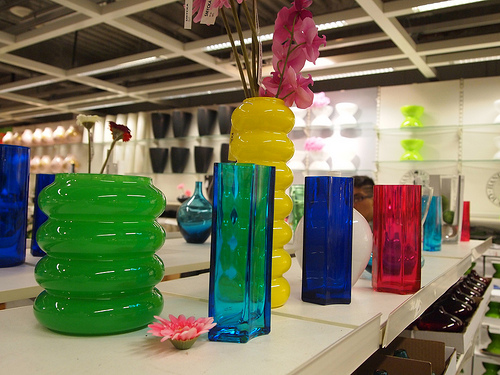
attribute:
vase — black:
[150, 113, 170, 140]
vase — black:
[166, 111, 189, 141]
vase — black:
[194, 109, 215, 136]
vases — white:
[301, 100, 373, 178]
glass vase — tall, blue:
[210, 164, 270, 340]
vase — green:
[40, 154, 158, 330]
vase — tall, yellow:
[224, 105, 294, 309]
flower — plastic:
[152, 294, 207, 343]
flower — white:
[79, 110, 97, 191]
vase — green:
[64, 179, 156, 310]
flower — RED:
[101, 116, 133, 174]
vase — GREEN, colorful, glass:
[34, 167, 171, 330]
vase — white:
[292, 203, 381, 291]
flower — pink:
[252, 7, 333, 111]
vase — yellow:
[226, 87, 303, 315]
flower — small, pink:
[143, 308, 225, 352]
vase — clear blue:
[215, 163, 275, 341]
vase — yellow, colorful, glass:
[218, 93, 306, 312]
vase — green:
[44, 170, 168, 340]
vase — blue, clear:
[207, 158, 273, 348]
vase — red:
[370, 173, 424, 306]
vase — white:
[291, 188, 378, 293]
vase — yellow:
[232, 93, 302, 323]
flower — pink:
[243, 3, 339, 110]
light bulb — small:
[429, 312, 469, 338]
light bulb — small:
[443, 293, 473, 316]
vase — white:
[291, 177, 385, 305]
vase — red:
[371, 177, 425, 290]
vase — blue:
[305, 173, 357, 307]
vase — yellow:
[222, 93, 305, 325]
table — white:
[28, 207, 437, 368]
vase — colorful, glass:
[203, 158, 288, 345]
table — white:
[62, 178, 465, 370]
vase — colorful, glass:
[298, 170, 364, 316]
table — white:
[102, 227, 482, 365]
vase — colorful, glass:
[366, 176, 433, 301]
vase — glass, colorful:
[412, 184, 453, 261]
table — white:
[127, 221, 483, 361]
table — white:
[108, 239, 483, 372]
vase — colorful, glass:
[450, 194, 482, 254]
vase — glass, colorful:
[171, 176, 222, 249]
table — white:
[1, 223, 477, 373]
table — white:
[94, 282, 476, 373]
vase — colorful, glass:
[25, 155, 65, 254]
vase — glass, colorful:
[1, 143, 31, 275]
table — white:
[32, 213, 481, 373]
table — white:
[110, 167, 480, 358]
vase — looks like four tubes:
[26, 163, 170, 336]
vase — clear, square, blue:
[204, 144, 281, 347]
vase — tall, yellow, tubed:
[228, 95, 293, 309]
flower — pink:
[281, 62, 317, 109]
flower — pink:
[288, 14, 328, 64]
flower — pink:
[282, 0, 312, 26]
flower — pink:
[254, 70, 283, 93]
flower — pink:
[182, 0, 207, 22]